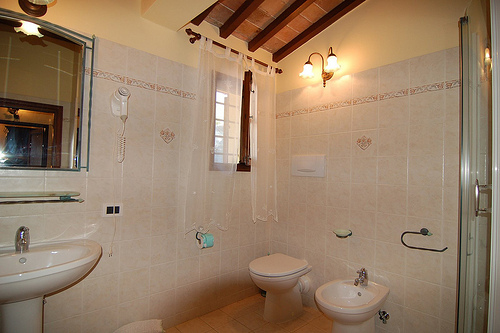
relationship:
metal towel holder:
[398, 227, 416, 244] [391, 222, 453, 267]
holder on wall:
[391, 222, 453, 267] [395, 127, 450, 208]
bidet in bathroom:
[318, 262, 393, 329] [17, 14, 483, 313]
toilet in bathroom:
[240, 242, 313, 324] [17, 14, 483, 313]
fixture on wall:
[299, 48, 343, 86] [395, 127, 450, 208]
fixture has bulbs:
[299, 48, 343, 86] [299, 53, 339, 78]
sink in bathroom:
[1, 217, 103, 332] [17, 14, 483, 313]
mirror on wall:
[2, 8, 103, 179] [100, 35, 144, 81]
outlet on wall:
[94, 196, 127, 221] [100, 35, 144, 81]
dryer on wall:
[96, 76, 141, 169] [100, 35, 144, 81]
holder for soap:
[325, 223, 356, 247] [337, 227, 346, 237]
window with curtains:
[206, 76, 248, 170] [197, 34, 279, 220]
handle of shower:
[469, 176, 495, 214] [455, 8, 499, 333]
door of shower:
[477, 11, 497, 329] [455, 8, 499, 333]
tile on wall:
[381, 129, 437, 214] [395, 127, 450, 208]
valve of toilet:
[377, 313, 393, 325] [240, 242, 313, 324]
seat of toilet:
[249, 248, 305, 282] [240, 242, 313, 324]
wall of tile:
[395, 127, 450, 208] [381, 129, 437, 214]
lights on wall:
[299, 48, 343, 86] [395, 127, 450, 208]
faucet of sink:
[12, 215, 45, 257] [1, 217, 103, 332]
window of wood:
[206, 76, 248, 170] [239, 70, 256, 174]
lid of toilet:
[249, 248, 305, 282] [240, 242, 313, 324]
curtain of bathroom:
[197, 34, 279, 220] [17, 14, 483, 313]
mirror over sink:
[2, 8, 103, 179] [1, 217, 103, 332]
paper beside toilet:
[199, 233, 217, 250] [240, 242, 313, 324]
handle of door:
[469, 176, 495, 214] [477, 11, 497, 329]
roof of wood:
[174, 1, 383, 61] [243, 5, 279, 35]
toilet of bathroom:
[240, 242, 313, 324] [17, 14, 483, 313]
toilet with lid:
[240, 242, 313, 324] [249, 248, 305, 282]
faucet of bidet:
[350, 263, 372, 288] [318, 262, 393, 329]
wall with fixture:
[395, 127, 450, 208] [299, 48, 343, 86]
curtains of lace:
[197, 34, 279, 220] [257, 62, 286, 222]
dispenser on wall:
[188, 225, 220, 249] [153, 226, 188, 261]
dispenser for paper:
[188, 225, 220, 249] [199, 233, 217, 250]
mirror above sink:
[2, 8, 103, 179] [1, 217, 103, 332]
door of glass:
[477, 11, 497, 329] [474, 46, 493, 174]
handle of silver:
[469, 176, 495, 214] [474, 182, 483, 218]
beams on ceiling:
[205, 3, 311, 54] [174, 1, 383, 61]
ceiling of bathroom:
[174, 1, 383, 61] [17, 14, 483, 313]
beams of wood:
[205, 3, 311, 54] [243, 5, 279, 35]